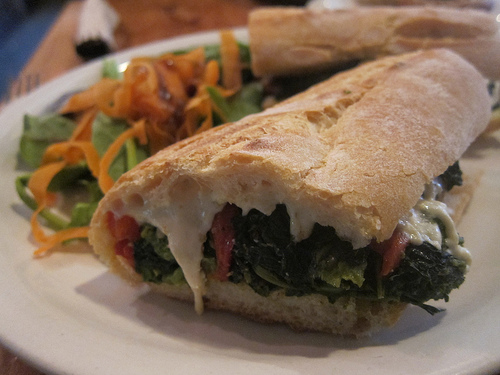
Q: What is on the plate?
A: Sandwich.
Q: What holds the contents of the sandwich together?
A: Bread.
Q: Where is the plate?
A: Beneath the food.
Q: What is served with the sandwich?
A: Salad.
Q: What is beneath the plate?
A: Table.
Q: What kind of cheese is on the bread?
A: Mozzarella.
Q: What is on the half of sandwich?
A: Spinach, Cheese, and Tomato.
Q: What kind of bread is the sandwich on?
A: A hard roll.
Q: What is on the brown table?
A: A plate of food.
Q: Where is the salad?
A: On the plate next to the sandwich.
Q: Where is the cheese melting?
A: On the sandwich.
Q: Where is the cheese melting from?
A: The top part of the sandwich.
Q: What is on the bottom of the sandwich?
A: Spinach, and tomato.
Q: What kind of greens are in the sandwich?
A: Spinach.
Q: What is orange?
A: Carrots.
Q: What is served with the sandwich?
A: A salad.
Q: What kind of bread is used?
A: A baguette.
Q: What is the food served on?
A: A plate.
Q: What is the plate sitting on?
A: A table.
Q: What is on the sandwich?
A: Spinach, tomato, and cheese.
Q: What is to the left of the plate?
A: A fork.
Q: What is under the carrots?
A: Spinach.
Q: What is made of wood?
A: The table.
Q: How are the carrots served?
A: In slivers.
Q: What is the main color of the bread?
A: Brown.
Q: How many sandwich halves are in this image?
A: Two.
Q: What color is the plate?
A: White.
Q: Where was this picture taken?
A: Restaurant.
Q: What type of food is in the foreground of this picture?
A: Sandwich.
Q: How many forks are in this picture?
A: Two.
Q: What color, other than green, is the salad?
A: Orange.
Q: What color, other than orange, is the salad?
A: Green.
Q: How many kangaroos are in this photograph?
A: Zero.